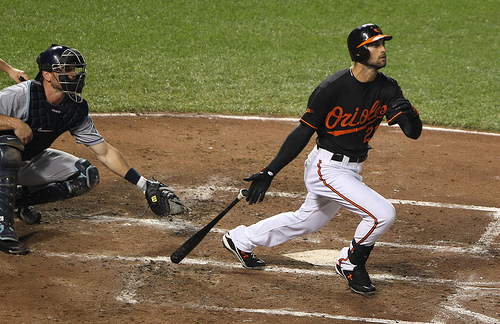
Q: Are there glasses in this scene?
A: No, there are no glasses.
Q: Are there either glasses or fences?
A: No, there are no glasses or fences.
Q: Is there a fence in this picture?
A: No, there are no fences.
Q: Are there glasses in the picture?
A: No, there are no glasses.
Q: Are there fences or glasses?
A: No, there are no glasses or fences.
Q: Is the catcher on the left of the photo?
A: Yes, the catcher is on the left of the image.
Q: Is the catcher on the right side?
A: No, the catcher is on the left of the image.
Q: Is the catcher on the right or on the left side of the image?
A: The catcher is on the left of the image.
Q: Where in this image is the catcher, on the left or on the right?
A: The catcher is on the left of the image.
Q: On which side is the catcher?
A: The catcher is on the left of the image.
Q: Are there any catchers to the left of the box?
A: Yes, there is a catcher to the left of the box.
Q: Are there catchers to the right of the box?
A: No, the catcher is to the left of the box.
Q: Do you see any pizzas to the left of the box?
A: No, there is a catcher to the left of the box.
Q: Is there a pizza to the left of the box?
A: No, there is a catcher to the left of the box.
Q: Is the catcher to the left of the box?
A: Yes, the catcher is to the left of the box.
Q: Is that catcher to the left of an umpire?
A: No, the catcher is to the left of the box.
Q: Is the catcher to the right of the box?
A: No, the catcher is to the left of the box.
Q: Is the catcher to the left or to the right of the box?
A: The catcher is to the left of the box.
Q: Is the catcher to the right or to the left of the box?
A: The catcher is to the left of the box.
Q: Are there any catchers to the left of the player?
A: Yes, there is a catcher to the left of the player.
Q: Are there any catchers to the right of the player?
A: No, the catcher is to the left of the player.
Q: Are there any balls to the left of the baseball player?
A: No, there is a catcher to the left of the player.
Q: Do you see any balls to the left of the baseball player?
A: No, there is a catcher to the left of the player.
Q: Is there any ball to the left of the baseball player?
A: No, there is a catcher to the left of the player.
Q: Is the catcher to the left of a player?
A: Yes, the catcher is to the left of a player.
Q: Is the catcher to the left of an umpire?
A: No, the catcher is to the left of a player.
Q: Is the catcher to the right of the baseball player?
A: No, the catcher is to the left of the player.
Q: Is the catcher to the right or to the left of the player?
A: The catcher is to the left of the player.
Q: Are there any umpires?
A: No, there are no umpires.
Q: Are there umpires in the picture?
A: No, there are no umpires.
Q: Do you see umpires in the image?
A: No, there are no umpires.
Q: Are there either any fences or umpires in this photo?
A: No, there are no umpires or fences.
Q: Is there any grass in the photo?
A: Yes, there is grass.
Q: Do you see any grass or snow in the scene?
A: Yes, there is grass.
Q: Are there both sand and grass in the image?
A: No, there is grass but no sand.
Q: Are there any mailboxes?
A: No, there are no mailboxes.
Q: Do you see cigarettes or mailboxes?
A: No, there are no mailboxes or cigarettes.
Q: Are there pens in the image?
A: No, there are no pens.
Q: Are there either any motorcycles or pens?
A: No, there are no pens or motorcycles.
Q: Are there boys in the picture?
A: No, there are no boys.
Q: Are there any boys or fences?
A: No, there are no boys or fences.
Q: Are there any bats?
A: Yes, there is a bat.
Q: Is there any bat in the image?
A: Yes, there is a bat.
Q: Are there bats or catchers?
A: Yes, there is a bat.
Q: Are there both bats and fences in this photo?
A: No, there is a bat but no fences.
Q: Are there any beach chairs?
A: No, there are no beach chairs.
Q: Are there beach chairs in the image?
A: No, there are no beach chairs.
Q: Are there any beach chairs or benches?
A: No, there are no beach chairs or benches.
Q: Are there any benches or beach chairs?
A: No, there are no beach chairs or benches.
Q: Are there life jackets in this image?
A: No, there are no life jackets.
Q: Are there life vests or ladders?
A: No, there are no life vests or ladders.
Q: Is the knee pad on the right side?
A: Yes, the knee pad is on the right of the image.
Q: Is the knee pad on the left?
A: No, the knee pad is on the right of the image.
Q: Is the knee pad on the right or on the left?
A: The knee pad is on the right of the image.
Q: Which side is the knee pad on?
A: The knee pad is on the right of the image.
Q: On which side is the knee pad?
A: The knee pad is on the right of the image.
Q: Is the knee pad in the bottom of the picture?
A: Yes, the knee pad is in the bottom of the image.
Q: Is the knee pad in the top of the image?
A: No, the knee pad is in the bottom of the image.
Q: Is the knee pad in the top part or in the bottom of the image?
A: The knee pad is in the bottom of the image.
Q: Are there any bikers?
A: No, there are no bikers.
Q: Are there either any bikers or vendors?
A: No, there are no bikers or vendors.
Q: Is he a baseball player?
A: Yes, this is a baseball player.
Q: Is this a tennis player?
A: No, this is a baseball player.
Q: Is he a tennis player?
A: No, this is a baseball player.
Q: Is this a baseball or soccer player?
A: This is a baseball player.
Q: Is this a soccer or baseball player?
A: This is a baseball player.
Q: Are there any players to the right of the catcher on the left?
A: Yes, there is a player to the right of the catcher.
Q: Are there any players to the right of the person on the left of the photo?
A: Yes, there is a player to the right of the catcher.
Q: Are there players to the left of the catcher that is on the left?
A: No, the player is to the right of the catcher.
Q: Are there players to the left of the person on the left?
A: No, the player is to the right of the catcher.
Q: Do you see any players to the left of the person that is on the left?
A: No, the player is to the right of the catcher.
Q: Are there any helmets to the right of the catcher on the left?
A: No, there is a player to the right of the catcher.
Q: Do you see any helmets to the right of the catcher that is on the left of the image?
A: No, there is a player to the right of the catcher.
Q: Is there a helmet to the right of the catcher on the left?
A: No, there is a player to the right of the catcher.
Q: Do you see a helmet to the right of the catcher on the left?
A: No, there is a player to the right of the catcher.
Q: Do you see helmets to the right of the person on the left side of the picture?
A: No, there is a player to the right of the catcher.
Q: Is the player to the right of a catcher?
A: Yes, the player is to the right of a catcher.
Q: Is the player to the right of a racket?
A: No, the player is to the right of a catcher.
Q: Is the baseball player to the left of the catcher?
A: No, the player is to the right of the catcher.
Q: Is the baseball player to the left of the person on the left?
A: No, the player is to the right of the catcher.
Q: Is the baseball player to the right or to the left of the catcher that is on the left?
A: The player is to the right of the catcher.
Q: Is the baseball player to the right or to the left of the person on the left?
A: The player is to the right of the catcher.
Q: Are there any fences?
A: No, there are no fences.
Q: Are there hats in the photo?
A: Yes, there is a hat.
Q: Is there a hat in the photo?
A: Yes, there is a hat.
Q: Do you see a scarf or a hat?
A: Yes, there is a hat.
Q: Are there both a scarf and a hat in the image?
A: No, there is a hat but no scarves.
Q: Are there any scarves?
A: No, there are no scarves.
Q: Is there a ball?
A: No, there are no balls.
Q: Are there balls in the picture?
A: No, there are no balls.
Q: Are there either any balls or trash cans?
A: No, there are no balls or trash cans.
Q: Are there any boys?
A: No, there are no boys.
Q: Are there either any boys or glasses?
A: No, there are no boys or glasses.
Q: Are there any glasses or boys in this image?
A: No, there are no boys or glasses.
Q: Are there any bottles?
A: No, there are no bottles.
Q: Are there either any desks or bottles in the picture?
A: No, there are no bottles or desks.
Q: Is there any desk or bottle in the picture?
A: No, there are no bottles or desks.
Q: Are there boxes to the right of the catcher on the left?
A: Yes, there is a box to the right of the catcher.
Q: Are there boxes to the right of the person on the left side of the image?
A: Yes, there is a box to the right of the catcher.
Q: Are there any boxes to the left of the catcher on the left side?
A: No, the box is to the right of the catcher.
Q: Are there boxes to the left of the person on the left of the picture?
A: No, the box is to the right of the catcher.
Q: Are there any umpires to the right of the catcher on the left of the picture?
A: No, there is a box to the right of the catcher.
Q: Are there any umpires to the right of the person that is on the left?
A: No, there is a box to the right of the catcher.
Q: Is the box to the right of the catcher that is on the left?
A: Yes, the box is to the right of the catcher.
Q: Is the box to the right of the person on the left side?
A: Yes, the box is to the right of the catcher.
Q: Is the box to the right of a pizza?
A: No, the box is to the right of the catcher.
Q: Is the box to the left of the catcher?
A: No, the box is to the right of the catcher.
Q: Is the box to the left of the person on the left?
A: No, the box is to the right of the catcher.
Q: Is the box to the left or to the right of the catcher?
A: The box is to the right of the catcher.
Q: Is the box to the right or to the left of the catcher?
A: The box is to the right of the catcher.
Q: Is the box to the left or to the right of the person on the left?
A: The box is to the right of the catcher.